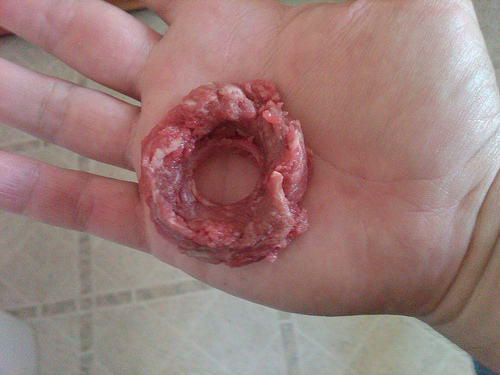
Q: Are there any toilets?
A: No, there are no toilets.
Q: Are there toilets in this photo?
A: No, there are no toilets.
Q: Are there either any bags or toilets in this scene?
A: No, there are no toilets or bags.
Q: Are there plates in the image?
A: No, there are no plates.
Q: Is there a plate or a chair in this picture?
A: No, there are no plates or chairs.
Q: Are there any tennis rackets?
A: No, there are no tennis rackets.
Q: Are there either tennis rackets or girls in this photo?
A: No, there are no tennis rackets or girls.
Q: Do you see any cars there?
A: No, there are no cars.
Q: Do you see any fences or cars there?
A: No, there are no cars or fences.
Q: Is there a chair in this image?
A: No, there are no chairs.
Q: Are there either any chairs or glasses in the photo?
A: No, there are no chairs or glasses.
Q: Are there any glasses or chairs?
A: No, there are no chairs or glasses.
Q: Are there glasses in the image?
A: No, there are no glasses.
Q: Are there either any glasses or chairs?
A: No, there are no glasses or chairs.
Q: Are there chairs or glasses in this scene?
A: No, there are no glasses or chairs.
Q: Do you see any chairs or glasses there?
A: No, there are no glasses or chairs.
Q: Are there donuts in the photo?
A: Yes, there is a donut.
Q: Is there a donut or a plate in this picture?
A: Yes, there is a donut.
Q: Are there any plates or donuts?
A: Yes, there is a donut.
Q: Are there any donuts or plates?
A: Yes, there is a donut.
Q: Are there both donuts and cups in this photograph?
A: No, there is a donut but no cups.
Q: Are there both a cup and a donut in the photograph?
A: No, there is a donut but no cups.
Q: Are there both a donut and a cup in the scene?
A: No, there is a donut but no cups.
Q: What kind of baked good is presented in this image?
A: The baked good is a donut.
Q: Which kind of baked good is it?
A: The food is a donut.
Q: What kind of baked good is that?
A: This is a donut.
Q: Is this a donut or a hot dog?
A: This is a donut.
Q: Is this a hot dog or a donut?
A: This is a donut.